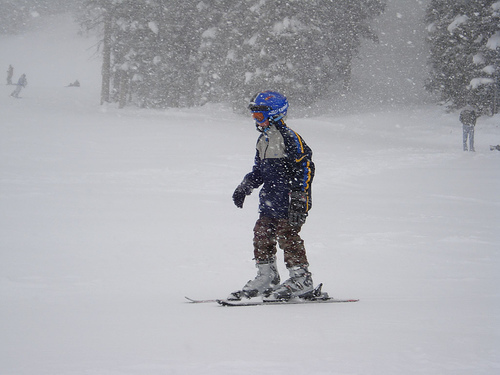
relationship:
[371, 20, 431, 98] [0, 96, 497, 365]
snow falling to field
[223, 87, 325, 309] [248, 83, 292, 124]
skier wearing helmet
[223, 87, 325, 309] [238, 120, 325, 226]
skier wears coat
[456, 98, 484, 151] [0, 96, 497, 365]
person on side of field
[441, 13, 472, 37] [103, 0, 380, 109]
snow over trees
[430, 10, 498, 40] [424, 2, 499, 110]
branches of tree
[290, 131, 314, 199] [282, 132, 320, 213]
stripe on sleeve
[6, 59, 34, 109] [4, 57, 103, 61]
skiers in background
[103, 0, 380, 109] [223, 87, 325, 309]
trees behind skier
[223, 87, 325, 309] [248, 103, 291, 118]
skier wearing goggles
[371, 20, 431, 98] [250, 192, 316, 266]
snow against pants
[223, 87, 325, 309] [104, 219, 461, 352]
skier in snow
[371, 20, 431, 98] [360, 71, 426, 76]
snow against background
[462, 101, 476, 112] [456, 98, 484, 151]
head of person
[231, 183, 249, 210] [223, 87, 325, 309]
hand of skier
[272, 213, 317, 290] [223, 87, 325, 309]
leg of skier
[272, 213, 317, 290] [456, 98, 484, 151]
leg of person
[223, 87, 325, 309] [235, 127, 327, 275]
skier in snow suit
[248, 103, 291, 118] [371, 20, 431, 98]
goggles for snow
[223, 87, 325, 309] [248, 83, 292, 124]
skier has helmet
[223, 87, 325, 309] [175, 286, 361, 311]
skier on skis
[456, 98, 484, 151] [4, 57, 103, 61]
person in background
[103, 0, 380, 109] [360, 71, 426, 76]
trees in background